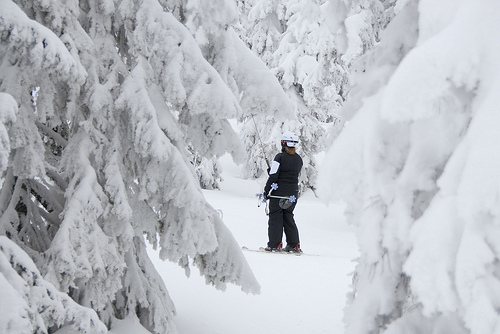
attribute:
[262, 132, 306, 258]
person — skiing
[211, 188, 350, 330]
snow — white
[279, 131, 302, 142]
hat — white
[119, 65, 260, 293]
branch — evergreen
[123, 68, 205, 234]
snow — white, heavy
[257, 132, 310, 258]
skier — taking break, not using poles, skiing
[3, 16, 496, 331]
forest — snow covered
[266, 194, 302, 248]
pants — black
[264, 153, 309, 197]
jacket — black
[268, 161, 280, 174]
patches — white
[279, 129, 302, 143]
helmet — white, plastic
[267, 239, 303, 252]
boots — black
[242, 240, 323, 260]
skiis — white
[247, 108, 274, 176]
pole — metal, silver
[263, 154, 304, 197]
coat — black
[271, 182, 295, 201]
baskets — blue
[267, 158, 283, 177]
patche — white